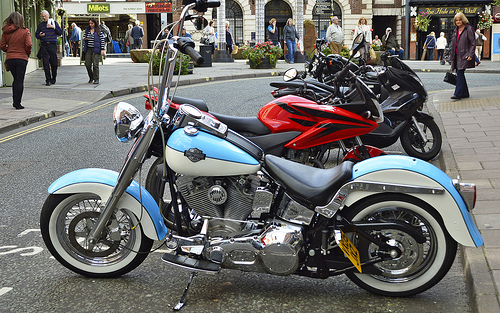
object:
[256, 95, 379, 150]
tank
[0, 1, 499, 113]
background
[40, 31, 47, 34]
phones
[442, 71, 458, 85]
bag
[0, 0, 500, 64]
building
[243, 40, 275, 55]
flowers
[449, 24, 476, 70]
jacket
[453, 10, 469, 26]
hair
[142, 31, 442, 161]
bike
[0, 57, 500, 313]
ground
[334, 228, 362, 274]
license plate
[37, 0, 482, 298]
bike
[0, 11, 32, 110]
people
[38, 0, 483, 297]
three bikes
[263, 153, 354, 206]
seat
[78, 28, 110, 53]
shirt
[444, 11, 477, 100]
woman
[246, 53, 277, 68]
planter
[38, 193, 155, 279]
motorcycle tire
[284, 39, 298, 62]
blue jeans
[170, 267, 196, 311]
kickstand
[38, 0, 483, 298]
motorbikes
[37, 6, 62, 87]
pepole are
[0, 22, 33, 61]
jacket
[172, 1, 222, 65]
handlebars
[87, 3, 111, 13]
sign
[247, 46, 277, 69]
pot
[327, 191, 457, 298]
tire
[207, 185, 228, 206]
gas tank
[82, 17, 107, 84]
people walking